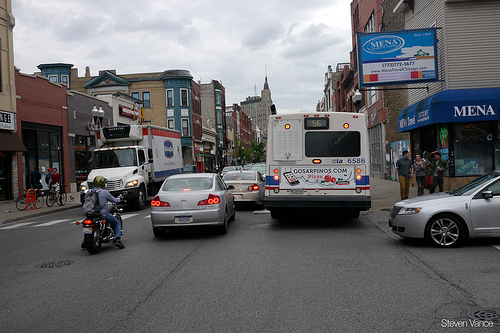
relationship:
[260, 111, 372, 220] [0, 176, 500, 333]
bus on road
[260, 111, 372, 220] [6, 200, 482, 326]
bus on road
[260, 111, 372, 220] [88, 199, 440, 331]
bus on road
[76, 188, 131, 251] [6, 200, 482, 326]
motorcycle on road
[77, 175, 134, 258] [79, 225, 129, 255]
man wearing shoes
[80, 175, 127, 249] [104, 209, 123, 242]
man wearing pants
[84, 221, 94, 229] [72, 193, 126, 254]
taillight on motorcycle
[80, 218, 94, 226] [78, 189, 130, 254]
taillight on motorcycle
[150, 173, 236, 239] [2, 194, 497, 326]
silver car on street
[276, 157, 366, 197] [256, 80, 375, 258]
letters on bus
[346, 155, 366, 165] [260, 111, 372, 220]
numbers on bus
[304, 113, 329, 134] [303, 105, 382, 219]
numbers on bus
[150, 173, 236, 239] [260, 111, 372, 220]
silver car next to bus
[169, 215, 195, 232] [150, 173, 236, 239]
plate on silver car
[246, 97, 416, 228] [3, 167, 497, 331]
bus on road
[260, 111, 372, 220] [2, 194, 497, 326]
bus on street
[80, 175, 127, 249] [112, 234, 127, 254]
man wearing shoes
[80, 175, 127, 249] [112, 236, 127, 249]
man wearing shoes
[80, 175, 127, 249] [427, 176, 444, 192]
man wearing pants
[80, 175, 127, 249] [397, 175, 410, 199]
man wearing pants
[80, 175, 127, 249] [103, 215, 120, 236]
man wearing pants